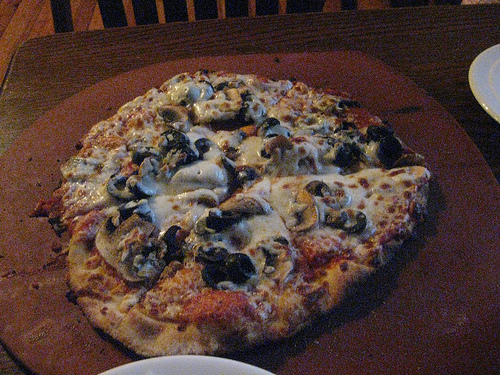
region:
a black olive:
[332, 193, 369, 246]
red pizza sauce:
[187, 273, 259, 325]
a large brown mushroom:
[107, 194, 164, 295]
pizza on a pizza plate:
[14, 54, 451, 365]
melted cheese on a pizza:
[167, 142, 249, 195]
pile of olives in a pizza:
[196, 233, 276, 307]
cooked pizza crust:
[302, 240, 363, 295]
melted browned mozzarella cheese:
[246, 157, 404, 237]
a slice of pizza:
[210, 149, 460, 326]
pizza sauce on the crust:
[18, 167, 79, 244]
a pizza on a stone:
[58, 66, 439, 348]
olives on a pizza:
[200, 245, 252, 289]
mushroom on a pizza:
[97, 218, 164, 281]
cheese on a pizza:
[174, 166, 223, 185]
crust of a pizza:
[114, 309, 306, 354]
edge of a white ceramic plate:
[469, 45, 496, 118]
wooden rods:
[1, 1, 348, 32]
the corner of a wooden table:
[7, 29, 106, 123]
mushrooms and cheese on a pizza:
[290, 183, 366, 234]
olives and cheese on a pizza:
[164, 131, 235, 181]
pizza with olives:
[45, 51, 442, 366]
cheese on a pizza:
[135, 108, 262, 225]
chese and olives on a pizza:
[120, 110, 320, 247]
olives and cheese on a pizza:
[101, 106, 309, 298]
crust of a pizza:
[63, 226, 174, 352]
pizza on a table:
[17, 56, 494, 366]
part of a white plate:
[463, 58, 493, 123]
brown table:
[33, 46, 223, 103]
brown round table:
[12, 16, 498, 371]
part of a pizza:
[306, 267, 330, 297]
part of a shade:
[407, 260, 425, 283]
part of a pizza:
[300, 213, 356, 295]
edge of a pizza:
[211, 351, 236, 366]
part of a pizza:
[206, 259, 268, 333]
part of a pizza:
[366, 300, 409, 353]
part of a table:
[461, 114, 481, 141]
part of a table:
[459, 95, 480, 135]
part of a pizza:
[256, 261, 313, 335]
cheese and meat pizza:
[50, 63, 449, 355]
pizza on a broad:
[20, 48, 455, 373]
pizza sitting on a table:
[15, 12, 468, 358]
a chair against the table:
[43, 0, 360, 37]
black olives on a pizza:
[195, 245, 260, 287]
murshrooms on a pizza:
[83, 206, 167, 274]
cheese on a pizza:
[160, 160, 234, 216]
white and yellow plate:
[473, 37, 499, 123]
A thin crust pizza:
[45, 263, 154, 340]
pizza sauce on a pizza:
[313, 227, 365, 262]